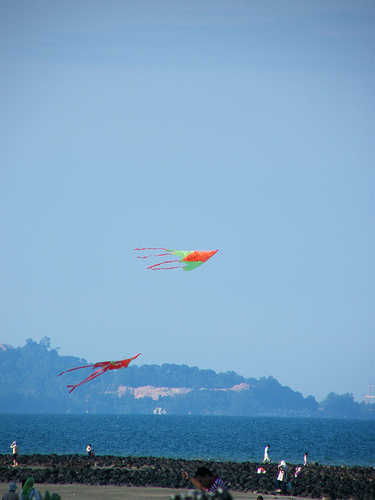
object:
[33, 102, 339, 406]
sky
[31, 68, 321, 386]
sky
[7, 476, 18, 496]
woman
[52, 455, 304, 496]
beach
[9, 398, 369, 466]
water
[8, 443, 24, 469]
people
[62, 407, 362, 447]
water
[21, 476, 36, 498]
woman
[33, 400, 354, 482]
water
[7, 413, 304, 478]
water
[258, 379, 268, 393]
trees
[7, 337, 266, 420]
sky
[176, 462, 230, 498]
man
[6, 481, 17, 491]
hat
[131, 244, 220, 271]
kite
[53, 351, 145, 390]
kite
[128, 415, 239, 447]
water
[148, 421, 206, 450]
waves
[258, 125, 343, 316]
sky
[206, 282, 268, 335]
sky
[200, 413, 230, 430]
sea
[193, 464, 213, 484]
head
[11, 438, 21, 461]
man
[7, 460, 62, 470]
shore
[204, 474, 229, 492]
shirt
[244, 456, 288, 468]
shore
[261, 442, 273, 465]
person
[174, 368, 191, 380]
forest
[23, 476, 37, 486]
hat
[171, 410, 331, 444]
ocean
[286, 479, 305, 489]
object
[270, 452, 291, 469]
scarf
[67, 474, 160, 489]
sand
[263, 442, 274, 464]
man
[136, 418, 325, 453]
water